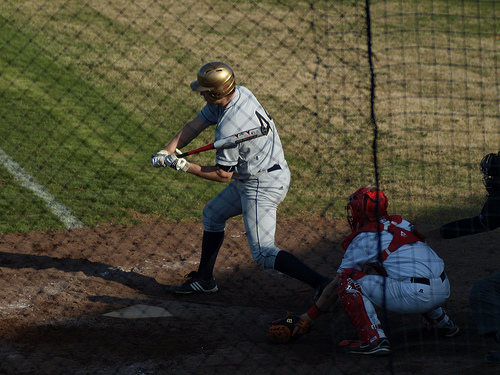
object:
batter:
[148, 55, 329, 297]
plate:
[105, 300, 178, 323]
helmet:
[187, 63, 237, 95]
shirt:
[195, 87, 282, 177]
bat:
[173, 123, 273, 157]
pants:
[197, 170, 289, 273]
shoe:
[165, 268, 221, 297]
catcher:
[268, 187, 460, 355]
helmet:
[343, 181, 384, 230]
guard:
[346, 193, 362, 232]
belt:
[405, 271, 453, 285]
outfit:
[343, 229, 447, 317]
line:
[3, 141, 87, 233]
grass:
[4, 8, 495, 224]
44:
[255, 103, 275, 132]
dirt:
[8, 219, 490, 371]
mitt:
[264, 308, 307, 340]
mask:
[341, 196, 361, 228]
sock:
[196, 229, 225, 277]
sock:
[276, 250, 324, 291]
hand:
[285, 305, 318, 339]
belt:
[260, 161, 285, 174]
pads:
[338, 277, 380, 341]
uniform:
[189, 86, 303, 269]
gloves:
[163, 153, 185, 170]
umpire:
[435, 151, 499, 251]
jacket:
[438, 199, 498, 233]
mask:
[475, 152, 492, 196]